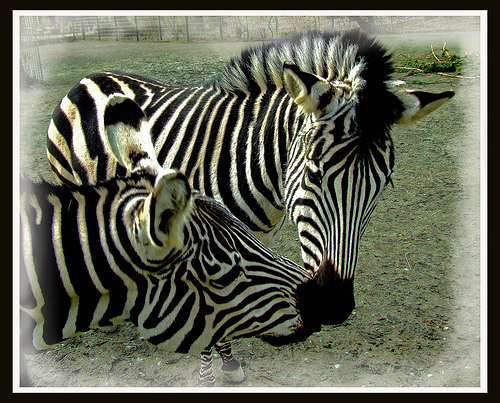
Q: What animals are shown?
A: Zebras.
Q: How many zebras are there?
A: 2.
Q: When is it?
A: Day time.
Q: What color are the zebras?
A: Black and white.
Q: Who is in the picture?
A: Only the zebras.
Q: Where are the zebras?
A: At the zoo.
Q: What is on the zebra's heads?
A: Hair.